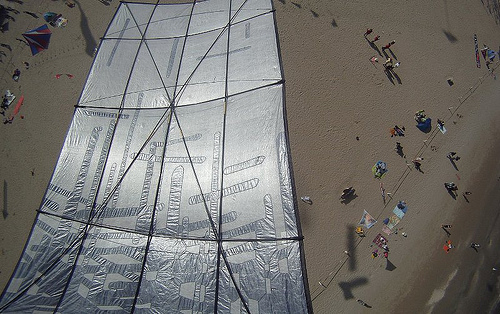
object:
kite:
[0, 0, 316, 314]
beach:
[0, 0, 499, 313]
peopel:
[380, 40, 397, 49]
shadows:
[392, 71, 404, 86]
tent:
[17, 23, 51, 57]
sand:
[0, 0, 499, 313]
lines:
[121, 3, 169, 99]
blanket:
[10, 94, 25, 115]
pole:
[223, 155, 267, 175]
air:
[275, 35, 358, 96]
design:
[164, 37, 179, 79]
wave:
[415, 267, 459, 313]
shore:
[388, 143, 499, 314]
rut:
[330, 20, 342, 29]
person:
[370, 35, 379, 42]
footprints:
[375, 83, 384, 88]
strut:
[142, 1, 158, 40]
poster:
[206, 59, 257, 96]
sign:
[355, 208, 380, 229]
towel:
[352, 226, 364, 235]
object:
[53, 73, 61, 79]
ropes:
[0, 0, 247, 313]